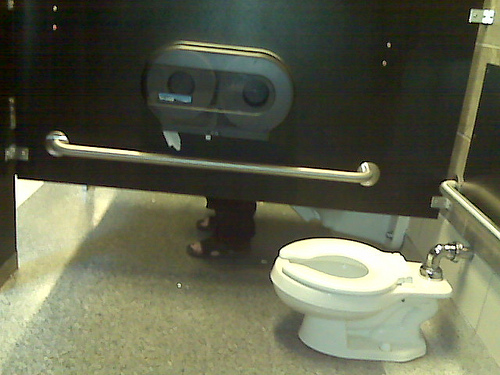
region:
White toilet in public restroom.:
[281, 231, 442, 373]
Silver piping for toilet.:
[420, 237, 469, 293]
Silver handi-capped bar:
[426, 174, 498, 251]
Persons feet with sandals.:
[143, 210, 269, 287]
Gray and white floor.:
[1, 278, 258, 368]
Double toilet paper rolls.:
[111, 12, 315, 174]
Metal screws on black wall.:
[338, 24, 408, 126]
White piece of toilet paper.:
[154, 50, 190, 155]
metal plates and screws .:
[0, 86, 39, 182]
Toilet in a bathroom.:
[234, 197, 486, 360]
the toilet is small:
[273, 222, 458, 369]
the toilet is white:
[250, 202, 467, 372]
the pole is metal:
[51, 116, 405, 194]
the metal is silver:
[50, 107, 379, 209]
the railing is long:
[39, 114, 391, 199]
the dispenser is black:
[140, 27, 317, 164]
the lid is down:
[261, 207, 431, 317]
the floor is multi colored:
[44, 279, 171, 346]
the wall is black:
[303, 21, 372, 104]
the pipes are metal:
[415, 230, 472, 285]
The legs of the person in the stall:
[183, 184, 258, 266]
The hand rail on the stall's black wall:
[38, 127, 380, 189]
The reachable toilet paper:
[159, 122, 183, 154]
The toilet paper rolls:
[129, 39, 297, 137]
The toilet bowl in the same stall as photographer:
[266, 239, 453, 362]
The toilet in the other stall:
[289, 202, 411, 253]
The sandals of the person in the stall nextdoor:
[192, 214, 244, 260]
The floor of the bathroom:
[2, 181, 498, 372]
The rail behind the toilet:
[440, 172, 498, 249]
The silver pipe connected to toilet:
[422, 240, 481, 285]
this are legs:
[185, 203, 255, 256]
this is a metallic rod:
[51, 144, 376, 187]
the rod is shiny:
[46, 142, 333, 194]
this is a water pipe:
[427, 241, 470, 258]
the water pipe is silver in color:
[426, 241, 468, 260]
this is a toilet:
[276, 245, 431, 350]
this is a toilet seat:
[272, 239, 406, 284]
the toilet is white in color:
[286, 248, 427, 352]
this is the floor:
[50, 242, 181, 364]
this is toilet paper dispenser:
[143, 43, 296, 149]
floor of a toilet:
[113, 299, 210, 360]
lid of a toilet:
[326, 277, 366, 300]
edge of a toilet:
[291, 291, 338, 310]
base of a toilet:
[309, 336, 371, 370]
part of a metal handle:
[231, 165, 331, 196]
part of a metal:
[435, 242, 456, 270]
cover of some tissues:
[204, 53, 280, 122]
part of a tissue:
[163, 136, 185, 153]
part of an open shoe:
[203, 244, 223, 261]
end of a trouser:
[211, 217, 248, 239]